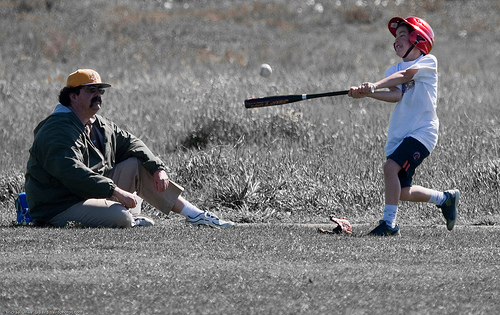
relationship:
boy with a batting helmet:
[244, 14, 462, 237] [388, 15, 433, 57]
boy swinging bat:
[244, 14, 462, 237] [240, 85, 376, 109]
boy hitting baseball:
[244, 14, 462, 237] [259, 64, 273, 80]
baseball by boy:
[259, 64, 273, 80] [244, 14, 462, 237]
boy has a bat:
[244, 14, 462, 237] [240, 85, 376, 109]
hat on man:
[61, 64, 112, 89] [21, 65, 242, 228]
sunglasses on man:
[79, 84, 106, 98] [21, 65, 242, 228]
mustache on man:
[86, 96, 104, 108] [21, 65, 242, 228]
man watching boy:
[21, 65, 242, 228] [244, 14, 462, 237]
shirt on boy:
[379, 56, 439, 155] [244, 14, 462, 237]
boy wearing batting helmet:
[244, 14, 462, 237] [388, 15, 433, 57]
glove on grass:
[315, 212, 355, 239] [1, 222, 499, 314]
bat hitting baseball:
[240, 85, 376, 109] [259, 64, 273, 80]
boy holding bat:
[244, 14, 462, 237] [240, 85, 376, 109]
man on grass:
[21, 65, 242, 228] [1, 222, 499, 314]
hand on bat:
[349, 83, 364, 100] [240, 85, 376, 109]